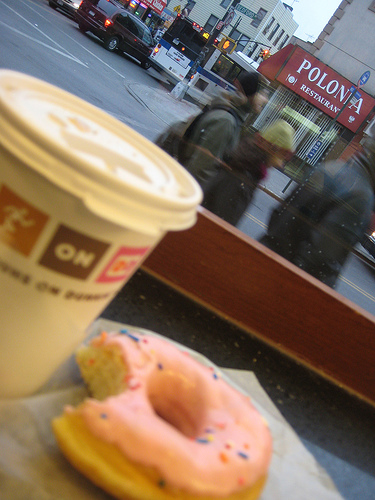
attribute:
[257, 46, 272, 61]
light — traffic, hanging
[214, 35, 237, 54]
sign — no walk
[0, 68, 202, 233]
lid — white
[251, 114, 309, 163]
cap — white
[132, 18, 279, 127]
bus — white, blue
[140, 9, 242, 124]
bus — blue, white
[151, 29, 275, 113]
bus — stopped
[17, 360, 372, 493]
table top — black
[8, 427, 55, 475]
paper — white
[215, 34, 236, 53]
crosswalk sign — yellow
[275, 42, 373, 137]
sign — Polonia Restaurant